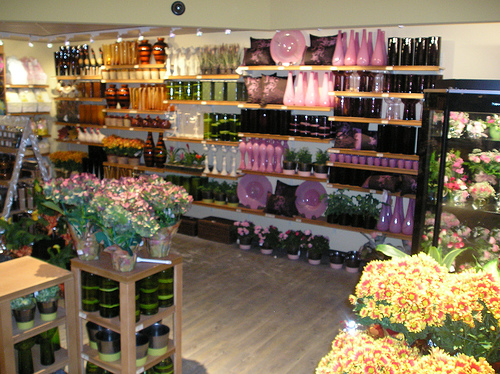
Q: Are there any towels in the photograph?
A: No, there are no towels.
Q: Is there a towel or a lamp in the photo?
A: No, there are no towels or lamps.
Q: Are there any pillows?
A: Yes, there is a pillow.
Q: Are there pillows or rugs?
A: Yes, there is a pillow.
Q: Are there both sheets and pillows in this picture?
A: No, there is a pillow but no sheets.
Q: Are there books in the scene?
A: No, there are no books.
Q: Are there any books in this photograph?
A: No, there are no books.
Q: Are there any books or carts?
A: No, there are no books or carts.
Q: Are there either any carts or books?
A: No, there are no books or carts.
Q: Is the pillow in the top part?
A: Yes, the pillow is in the top of the image.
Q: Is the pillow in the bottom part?
A: No, the pillow is in the top of the image.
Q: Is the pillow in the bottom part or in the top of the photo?
A: The pillow is in the top of the image.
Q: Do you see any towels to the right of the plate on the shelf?
A: No, there is a pillow to the right of the plate.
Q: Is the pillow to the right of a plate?
A: Yes, the pillow is to the right of a plate.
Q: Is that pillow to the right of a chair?
A: No, the pillow is to the right of a plate.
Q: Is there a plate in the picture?
A: Yes, there is a plate.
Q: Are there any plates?
A: Yes, there is a plate.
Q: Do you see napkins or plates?
A: Yes, there is a plate.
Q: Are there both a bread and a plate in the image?
A: No, there is a plate but no breads.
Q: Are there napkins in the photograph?
A: No, there are no napkins.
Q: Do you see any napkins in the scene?
A: No, there are no napkins.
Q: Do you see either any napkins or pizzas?
A: No, there are no napkins or pizzas.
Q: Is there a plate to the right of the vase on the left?
A: Yes, there is a plate to the right of the vase.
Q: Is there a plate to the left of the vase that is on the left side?
A: No, the plate is to the right of the vase.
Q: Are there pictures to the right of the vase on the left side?
A: No, there is a plate to the right of the vase.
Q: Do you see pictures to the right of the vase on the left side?
A: No, there is a plate to the right of the vase.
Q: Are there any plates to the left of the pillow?
A: Yes, there is a plate to the left of the pillow.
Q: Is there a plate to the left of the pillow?
A: Yes, there is a plate to the left of the pillow.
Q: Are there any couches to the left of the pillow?
A: No, there is a plate to the left of the pillow.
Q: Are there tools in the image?
A: No, there are no tools.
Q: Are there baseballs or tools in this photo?
A: No, there are no tools or baseballs.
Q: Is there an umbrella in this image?
A: No, there are no umbrellas.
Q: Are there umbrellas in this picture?
A: No, there are no umbrellas.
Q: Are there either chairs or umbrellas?
A: No, there are no umbrellas or chairs.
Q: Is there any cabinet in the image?
A: No, there are no cabinets.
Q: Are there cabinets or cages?
A: No, there are no cabinets or cages.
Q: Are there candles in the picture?
A: No, there are no candles.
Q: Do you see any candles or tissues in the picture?
A: No, there are no candles or tissues.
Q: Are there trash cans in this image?
A: No, there are no trash cans.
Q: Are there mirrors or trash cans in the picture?
A: No, there are no trash cans or mirrors.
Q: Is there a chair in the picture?
A: No, there are no chairs.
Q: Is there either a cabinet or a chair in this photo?
A: No, there are no chairs or cabinets.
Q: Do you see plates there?
A: Yes, there is a plate.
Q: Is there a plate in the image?
A: Yes, there is a plate.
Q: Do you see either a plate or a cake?
A: Yes, there is a plate.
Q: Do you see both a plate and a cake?
A: No, there is a plate but no cakes.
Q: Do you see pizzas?
A: No, there are no pizzas.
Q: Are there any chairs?
A: No, there are no chairs.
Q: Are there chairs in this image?
A: No, there are no chairs.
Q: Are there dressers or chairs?
A: No, there are no chairs or dressers.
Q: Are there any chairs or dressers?
A: No, there are no chairs or dressers.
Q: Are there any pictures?
A: No, there are no pictures.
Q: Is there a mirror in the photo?
A: No, there are no mirrors.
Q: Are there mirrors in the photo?
A: No, there are no mirrors.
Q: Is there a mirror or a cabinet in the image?
A: No, there are no mirrors or cabinets.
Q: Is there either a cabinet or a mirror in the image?
A: No, there are no mirrors or cabinets.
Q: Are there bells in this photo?
A: No, there are no bells.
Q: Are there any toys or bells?
A: No, there are no bells or toys.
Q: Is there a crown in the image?
A: No, there are no crowns.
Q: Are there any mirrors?
A: No, there are no mirrors.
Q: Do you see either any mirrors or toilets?
A: No, there are no mirrors or toilets.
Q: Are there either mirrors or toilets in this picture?
A: No, there are no mirrors or toilets.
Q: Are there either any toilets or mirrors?
A: No, there are no mirrors or toilets.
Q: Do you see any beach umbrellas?
A: No, there are no beach umbrellas.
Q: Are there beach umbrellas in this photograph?
A: No, there are no beach umbrellas.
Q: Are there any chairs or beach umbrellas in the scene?
A: No, there are no beach umbrellas or chairs.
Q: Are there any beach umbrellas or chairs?
A: No, there are no beach umbrellas or chairs.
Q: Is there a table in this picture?
A: Yes, there is a table.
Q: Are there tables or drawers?
A: Yes, there is a table.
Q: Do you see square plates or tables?
A: Yes, there is a square table.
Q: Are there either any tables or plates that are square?
A: Yes, the table is square.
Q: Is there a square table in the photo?
A: Yes, there is a square table.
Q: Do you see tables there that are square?
A: Yes, there is a table that is square.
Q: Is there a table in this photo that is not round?
A: Yes, there is a square table.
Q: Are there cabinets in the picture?
A: No, there are no cabinets.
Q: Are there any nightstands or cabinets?
A: No, there are no cabinets or nightstands.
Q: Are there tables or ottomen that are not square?
A: No, there is a table but it is square.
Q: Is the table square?
A: Yes, the table is square.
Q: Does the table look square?
A: Yes, the table is square.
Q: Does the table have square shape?
A: Yes, the table is square.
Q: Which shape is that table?
A: The table is square.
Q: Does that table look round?
A: No, the table is square.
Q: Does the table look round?
A: No, the table is square.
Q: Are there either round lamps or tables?
A: No, there is a table but it is square.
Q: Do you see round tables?
A: No, there is a table but it is square.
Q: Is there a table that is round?
A: No, there is a table but it is square.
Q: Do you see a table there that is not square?
A: No, there is a table but it is square.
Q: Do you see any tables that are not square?
A: No, there is a table but it is square.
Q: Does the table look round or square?
A: The table is square.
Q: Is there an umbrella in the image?
A: No, there are no umbrellas.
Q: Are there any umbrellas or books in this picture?
A: No, there are no umbrellas or books.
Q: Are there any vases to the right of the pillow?
A: Yes, there is a vase to the right of the pillow.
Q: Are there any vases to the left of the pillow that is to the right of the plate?
A: No, the vase is to the right of the pillow.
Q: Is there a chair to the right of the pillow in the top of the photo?
A: No, there is a vase to the right of the pillow.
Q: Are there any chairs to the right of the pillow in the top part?
A: No, there is a vase to the right of the pillow.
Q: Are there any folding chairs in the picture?
A: No, there are no folding chairs.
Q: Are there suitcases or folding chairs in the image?
A: No, there are no folding chairs or suitcases.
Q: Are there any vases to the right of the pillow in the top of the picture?
A: Yes, there is a vase to the right of the pillow.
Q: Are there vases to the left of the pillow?
A: No, the vase is to the right of the pillow.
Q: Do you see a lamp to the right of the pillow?
A: No, there is a vase to the right of the pillow.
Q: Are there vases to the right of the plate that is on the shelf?
A: Yes, there is a vase to the right of the plate.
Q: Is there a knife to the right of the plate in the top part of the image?
A: No, there is a vase to the right of the plate.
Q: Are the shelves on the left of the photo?
A: Yes, the shelves are on the left of the image.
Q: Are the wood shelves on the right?
A: No, the shelves are on the left of the image.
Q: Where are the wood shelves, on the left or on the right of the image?
A: The shelves are on the left of the image.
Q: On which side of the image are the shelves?
A: The shelves are on the left of the image.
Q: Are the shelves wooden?
A: Yes, the shelves are wooden.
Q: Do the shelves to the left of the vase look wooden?
A: Yes, the shelves are wooden.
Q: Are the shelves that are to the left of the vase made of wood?
A: Yes, the shelves are made of wood.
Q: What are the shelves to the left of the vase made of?
A: The shelves are made of wood.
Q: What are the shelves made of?
A: The shelves are made of wood.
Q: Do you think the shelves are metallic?
A: No, the shelves are wooden.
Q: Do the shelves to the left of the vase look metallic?
A: No, the shelves are wooden.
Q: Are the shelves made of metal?
A: No, the shelves are made of wood.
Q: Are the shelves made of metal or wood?
A: The shelves are made of wood.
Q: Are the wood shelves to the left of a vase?
A: Yes, the shelves are to the left of a vase.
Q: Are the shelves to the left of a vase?
A: Yes, the shelves are to the left of a vase.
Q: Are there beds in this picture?
A: No, there are no beds.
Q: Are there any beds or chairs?
A: No, there are no beds or chairs.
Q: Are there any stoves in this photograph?
A: No, there are no stoves.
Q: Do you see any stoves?
A: No, there are no stoves.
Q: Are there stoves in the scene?
A: No, there are no stoves.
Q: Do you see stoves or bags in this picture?
A: No, there are no stoves or bags.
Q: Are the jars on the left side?
A: Yes, the jars are on the left of the image.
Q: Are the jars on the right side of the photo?
A: No, the jars are on the left of the image.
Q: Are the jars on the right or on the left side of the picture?
A: The jars are on the left of the image.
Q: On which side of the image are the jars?
A: The jars are on the left of the image.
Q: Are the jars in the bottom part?
A: Yes, the jars are in the bottom of the image.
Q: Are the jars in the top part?
A: No, the jars are in the bottom of the image.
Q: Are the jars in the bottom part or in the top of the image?
A: The jars are in the bottom of the image.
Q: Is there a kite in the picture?
A: No, there are no kites.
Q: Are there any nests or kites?
A: No, there are no kites or nests.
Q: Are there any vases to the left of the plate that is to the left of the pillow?
A: Yes, there is a vase to the left of the plate.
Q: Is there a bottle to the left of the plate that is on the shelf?
A: No, there is a vase to the left of the plate.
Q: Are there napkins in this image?
A: No, there are no napkins.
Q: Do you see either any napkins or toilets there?
A: No, there are no napkins or toilets.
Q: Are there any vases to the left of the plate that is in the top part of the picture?
A: Yes, there is a vase to the left of the plate.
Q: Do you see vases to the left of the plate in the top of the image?
A: Yes, there is a vase to the left of the plate.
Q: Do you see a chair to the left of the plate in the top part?
A: No, there is a vase to the left of the plate.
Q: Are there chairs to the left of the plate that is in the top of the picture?
A: No, there is a vase to the left of the plate.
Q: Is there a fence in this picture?
A: No, there are no fences.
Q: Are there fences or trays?
A: No, there are no fences or trays.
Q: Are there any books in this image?
A: No, there are no books.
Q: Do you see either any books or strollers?
A: No, there are no books or strollers.